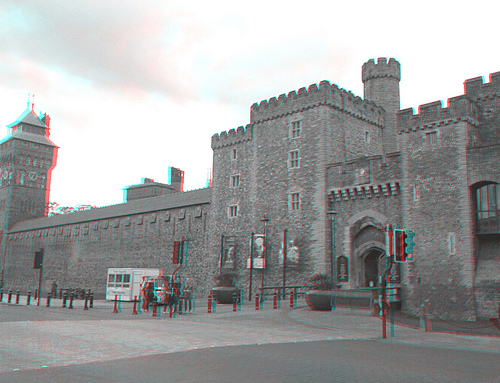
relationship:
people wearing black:
[139, 275, 201, 314] [139, 283, 161, 301]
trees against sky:
[44, 194, 104, 219] [0, 0, 500, 217]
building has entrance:
[206, 45, 475, 314] [344, 205, 394, 292]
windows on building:
[282, 111, 303, 220] [206, 45, 475, 314]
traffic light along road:
[377, 216, 413, 336] [2, 311, 436, 376]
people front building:
[137, 267, 198, 317] [175, 51, 485, 318]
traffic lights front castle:
[164, 227, 411, 268] [197, 45, 491, 323]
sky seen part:
[0, 0, 500, 217] [264, 329, 304, 352]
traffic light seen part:
[392, 223, 408, 263] [393, 251, 402, 261]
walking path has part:
[79, 313, 360, 373] [184, 329, 209, 350]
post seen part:
[375, 276, 391, 337] [379, 287, 386, 297]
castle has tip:
[193, 40, 485, 294] [357, 49, 402, 72]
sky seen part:
[62, 60, 158, 174] [72, 140, 97, 165]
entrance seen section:
[359, 242, 391, 296] [372, 254, 384, 270]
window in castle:
[284, 147, 304, 172] [201, 42, 471, 316]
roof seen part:
[10, 104, 46, 127] [30, 116, 40, 126]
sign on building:
[217, 126, 247, 155] [27, 108, 484, 346]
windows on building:
[187, 114, 324, 237] [5, 60, 469, 350]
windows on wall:
[180, 121, 358, 249] [102, 235, 173, 272]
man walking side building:
[369, 280, 384, 316] [5, 60, 469, 350]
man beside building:
[360, 256, 384, 316] [5, 60, 469, 350]